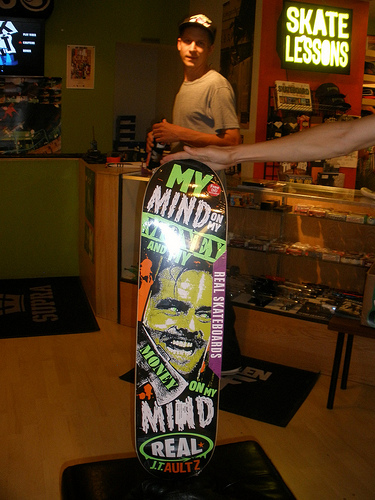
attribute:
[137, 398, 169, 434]
letter — white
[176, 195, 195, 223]
letter — white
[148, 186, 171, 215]
letter — white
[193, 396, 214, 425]
letter — white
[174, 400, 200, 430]
letter — white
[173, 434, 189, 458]
letter — white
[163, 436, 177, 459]
letter — white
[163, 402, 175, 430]
letter — white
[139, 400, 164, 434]
letter — white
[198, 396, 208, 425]
letter — white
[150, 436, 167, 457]
letter — white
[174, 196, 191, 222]
letter — white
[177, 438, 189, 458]
letter — white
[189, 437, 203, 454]
letter — white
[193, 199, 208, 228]
letter — white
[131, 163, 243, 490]
skateboard deck — colorful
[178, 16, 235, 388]
man — looking 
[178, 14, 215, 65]
head — man's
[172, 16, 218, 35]
hat — black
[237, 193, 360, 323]
case — glass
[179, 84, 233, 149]
shirt — grey, tee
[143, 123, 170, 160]
hand — man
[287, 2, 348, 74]
sign — neon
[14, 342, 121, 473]
floor — wooden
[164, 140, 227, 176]
hand — persons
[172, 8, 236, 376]
man — wearing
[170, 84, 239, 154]
shirt — grey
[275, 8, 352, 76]
sign —  light , green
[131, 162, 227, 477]
board — multiple, colored , skate 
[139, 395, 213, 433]
word — mind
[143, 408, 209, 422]
text — white, creepy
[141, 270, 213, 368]
face — jack nicholson's 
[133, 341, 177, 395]
word — money,  block , type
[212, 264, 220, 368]
words — real skateboards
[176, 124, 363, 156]
arm — outstretched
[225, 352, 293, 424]
rug — black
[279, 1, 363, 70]
sign — neon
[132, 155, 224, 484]
skateboard — My mind on my money and my money on my mind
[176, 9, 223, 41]
hat — black, white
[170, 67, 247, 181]
shirt — grey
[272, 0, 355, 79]
sign — bright, neon, skate lesson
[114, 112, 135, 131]
shelf — black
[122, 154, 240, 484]
skateboard — tall, decorative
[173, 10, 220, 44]
cap — black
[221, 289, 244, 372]
pants — black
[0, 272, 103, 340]
mat — black, floor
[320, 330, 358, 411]
legs — slim, blue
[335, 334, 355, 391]
leg — slim, blue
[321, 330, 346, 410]
leg — slim, blue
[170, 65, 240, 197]
shirt — short sleeve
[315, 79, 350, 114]
caps — stacked, black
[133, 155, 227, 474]
snowboard — big